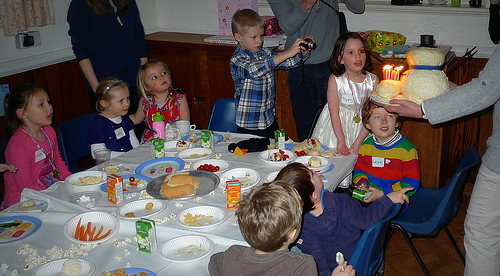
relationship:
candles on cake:
[351, 55, 414, 97] [411, 47, 459, 110]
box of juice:
[127, 219, 151, 232] [130, 209, 170, 251]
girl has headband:
[72, 65, 153, 160] [92, 81, 142, 104]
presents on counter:
[195, 19, 402, 57] [198, 40, 287, 82]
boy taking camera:
[239, 21, 332, 137] [299, 38, 318, 52]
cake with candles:
[411, 47, 459, 110] [351, 55, 414, 97]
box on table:
[127, 219, 151, 232] [91, 146, 264, 257]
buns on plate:
[164, 171, 202, 204] [161, 206, 230, 231]